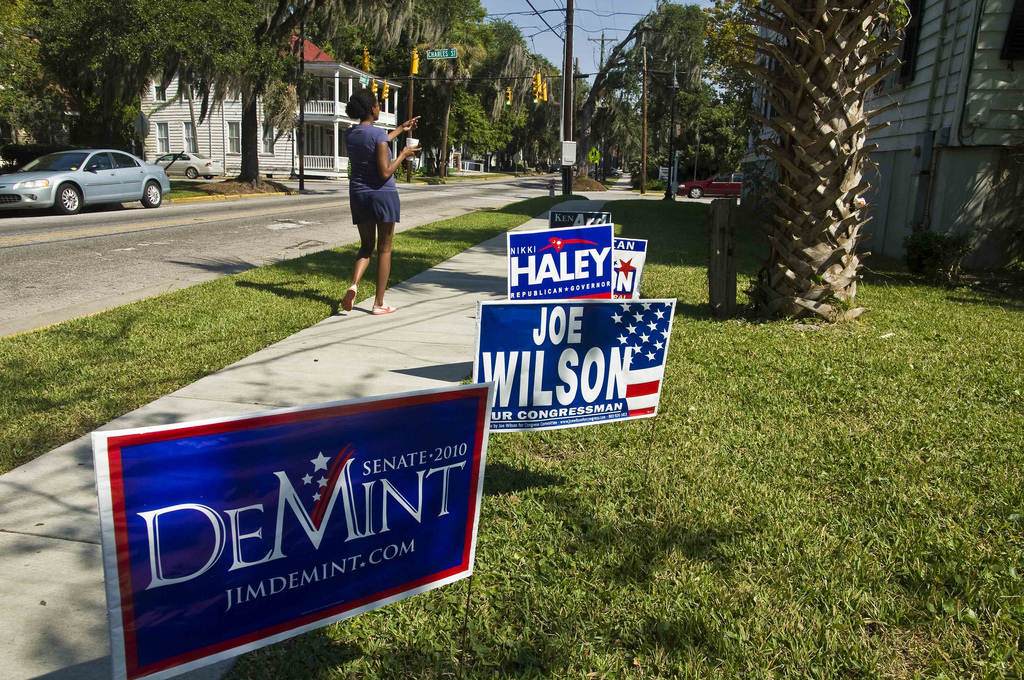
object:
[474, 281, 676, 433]
sign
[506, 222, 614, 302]
sign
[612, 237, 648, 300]
sign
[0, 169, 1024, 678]
ground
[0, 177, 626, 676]
sidewalk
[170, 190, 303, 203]
curb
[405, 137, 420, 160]
cup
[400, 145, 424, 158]
hand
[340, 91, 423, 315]
woman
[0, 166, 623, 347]
street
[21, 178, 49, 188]
headlight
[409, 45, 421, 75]
lights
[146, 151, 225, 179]
car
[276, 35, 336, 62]
roof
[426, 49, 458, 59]
sign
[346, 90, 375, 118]
hair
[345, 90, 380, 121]
head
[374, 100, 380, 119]
face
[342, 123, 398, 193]
torso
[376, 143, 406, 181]
arm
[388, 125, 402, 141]
arm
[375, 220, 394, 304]
legs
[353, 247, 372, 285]
calves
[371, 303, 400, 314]
shoes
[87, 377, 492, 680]
sign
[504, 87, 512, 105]
signal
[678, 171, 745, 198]
car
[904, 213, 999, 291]
bush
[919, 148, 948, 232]
meter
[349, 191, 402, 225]
shorts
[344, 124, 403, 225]
clothing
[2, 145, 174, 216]
car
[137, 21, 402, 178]
building